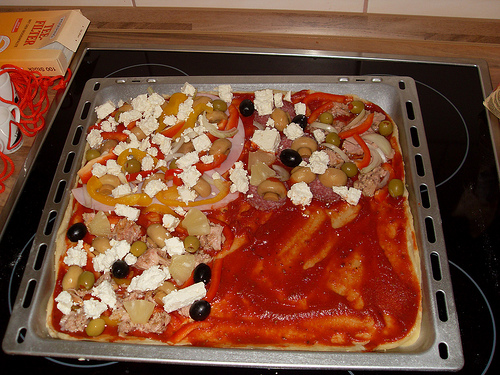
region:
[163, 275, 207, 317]
Feta cheese next to black olive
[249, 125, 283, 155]
Feta cheese next to black olive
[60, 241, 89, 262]
Feta cheese next to black olive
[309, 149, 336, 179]
Feta cheese next to black olive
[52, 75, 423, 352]
Uncooked pizza sitting in metal baking tray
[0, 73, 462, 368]
Metal baking tray sitting on top of stove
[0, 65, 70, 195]
Long red tangled string next to box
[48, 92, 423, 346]
Red tomato sauce covering all of pizza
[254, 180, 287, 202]
Small mushroom next to feta cheese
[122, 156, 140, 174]
Green olive next to long yellow pepper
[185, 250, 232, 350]
black olives on pizza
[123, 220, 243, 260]
green olives on pizza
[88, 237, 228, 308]
riccotta cheese on pizza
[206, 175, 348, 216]
large mushrooms on pizza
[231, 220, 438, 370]
red pizza sauce on pizza crust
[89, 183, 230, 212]
yellow peppers on pizza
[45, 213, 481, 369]
pizza pan is square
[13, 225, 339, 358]
pizza pan is silver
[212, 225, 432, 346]
pizza is not done yet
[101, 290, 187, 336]
pineapple tidbits on pizza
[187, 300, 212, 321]
A black shinny olive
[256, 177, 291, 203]
A small mushroom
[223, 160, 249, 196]
A piece of crubled feta cheese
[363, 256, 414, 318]
Red pizza sauce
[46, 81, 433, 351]
A square uncooked pizza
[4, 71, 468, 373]
A square pizza pan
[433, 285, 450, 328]
A oval hole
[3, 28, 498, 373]
A black stove top with a silver edge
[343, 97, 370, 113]
A green olive with a red pit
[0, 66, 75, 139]
Orange string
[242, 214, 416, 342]
dark red tomato sauce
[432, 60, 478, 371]
electric stove top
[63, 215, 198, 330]
three different kind of olives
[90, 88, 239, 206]
feta cheese and yellow bell pepper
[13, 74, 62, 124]
bright red string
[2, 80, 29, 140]
two white mugs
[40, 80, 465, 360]
aluminum food container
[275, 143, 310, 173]
pitch black whole olive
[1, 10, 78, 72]
box of white filters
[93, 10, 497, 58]
wooden trim lining the wall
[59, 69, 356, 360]
The pizza is homemade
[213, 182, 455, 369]
One section of the pizza is left plain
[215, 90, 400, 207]
The pizza is supreme style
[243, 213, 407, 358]
The sauce is smeared around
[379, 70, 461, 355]
The pan is silver and very thin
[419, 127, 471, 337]
The stove top is black and clean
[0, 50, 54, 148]
There is string on the counter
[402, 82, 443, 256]
The pan has holes in it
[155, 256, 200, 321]
Chunk of cheese on the pizza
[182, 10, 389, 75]
There is wood around the stove